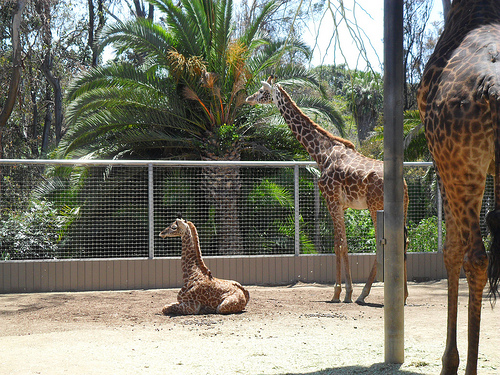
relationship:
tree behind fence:
[27, 4, 372, 254] [3, 147, 498, 277]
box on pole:
[374, 208, 389, 281] [378, 1, 409, 373]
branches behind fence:
[282, 0, 383, 134] [0, 160, 499, 286]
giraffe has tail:
[213, 62, 415, 312] [387, 187, 427, 259]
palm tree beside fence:
[55, 1, 350, 256] [4, 149, 499, 292]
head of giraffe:
[153, 215, 214, 257] [136, 222, 294, 325]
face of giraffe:
[151, 213, 187, 243] [152, 207, 252, 318]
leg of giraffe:
[451, 200, 496, 363] [413, 42, 498, 300]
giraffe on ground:
[246, 75, 409, 304] [326, 87, 373, 117]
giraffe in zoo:
[246, 75, 409, 304] [27, 10, 398, 372]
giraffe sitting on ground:
[152, 207, 252, 318] [107, 313, 320, 358]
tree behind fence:
[0, 0, 498, 257] [0, 160, 499, 286]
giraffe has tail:
[416, 0, 498, 375] [484, 139, 499, 311]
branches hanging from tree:
[308, 5, 373, 57] [107, 19, 250, 128]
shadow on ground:
[300, 309, 396, 374] [285, 336, 326, 357]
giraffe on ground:
[159, 213, 250, 314] [0, 276, 500, 373]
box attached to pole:
[376, 210, 386, 282] [335, 36, 457, 350]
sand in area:
[0, 274, 499, 374] [0, 158, 498, 373]